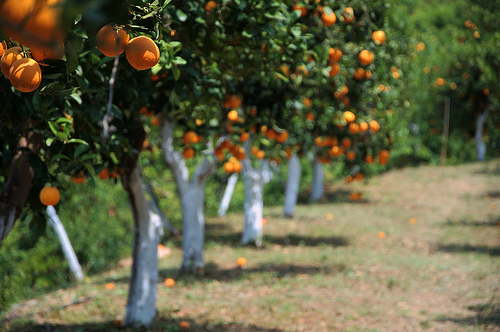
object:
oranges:
[220, 142, 238, 151]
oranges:
[225, 109, 245, 122]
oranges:
[185, 148, 200, 162]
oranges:
[328, 145, 348, 156]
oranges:
[355, 67, 366, 82]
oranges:
[315, 137, 335, 150]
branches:
[102, 58, 119, 139]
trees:
[414, 0, 495, 164]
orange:
[183, 131, 202, 147]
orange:
[206, 0, 225, 11]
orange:
[256, 151, 268, 160]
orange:
[0, 47, 32, 78]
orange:
[0, 42, 22, 55]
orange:
[356, 173, 365, 180]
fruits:
[184, 130, 200, 143]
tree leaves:
[40, 52, 136, 156]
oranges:
[185, 131, 202, 148]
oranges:
[33, 49, 63, 65]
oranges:
[323, 46, 346, 66]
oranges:
[371, 30, 391, 45]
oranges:
[349, 123, 361, 132]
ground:
[0, 160, 499, 331]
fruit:
[236, 256, 248, 266]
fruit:
[236, 257, 248, 266]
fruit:
[378, 232, 386, 238]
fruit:
[234, 148, 247, 160]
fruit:
[326, 213, 334, 220]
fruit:
[104, 282, 116, 290]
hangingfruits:
[28, 37, 66, 67]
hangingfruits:
[96, 23, 132, 58]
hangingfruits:
[8, 57, 42, 92]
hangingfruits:
[39, 183, 61, 206]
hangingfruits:
[232, 162, 243, 172]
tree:
[134, 0, 307, 272]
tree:
[258, 0, 345, 216]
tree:
[279, 0, 348, 218]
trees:
[3, 180, 89, 284]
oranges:
[254, 150, 270, 159]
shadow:
[267, 233, 352, 251]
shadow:
[203, 262, 341, 282]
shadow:
[436, 238, 499, 260]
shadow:
[445, 303, 500, 332]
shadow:
[474, 184, 500, 200]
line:
[163, 127, 206, 278]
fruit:
[370, 27, 388, 48]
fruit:
[357, 49, 373, 64]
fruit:
[325, 47, 342, 62]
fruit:
[328, 62, 340, 79]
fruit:
[342, 111, 356, 123]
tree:
[307, 0, 397, 205]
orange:
[294, 2, 313, 17]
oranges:
[431, 78, 449, 88]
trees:
[187, 0, 319, 246]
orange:
[150, 71, 169, 83]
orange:
[97, 167, 118, 180]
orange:
[71, 170, 85, 185]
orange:
[147, 114, 164, 127]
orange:
[371, 30, 391, 44]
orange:
[140, 138, 155, 151]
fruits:
[125, 35, 160, 70]